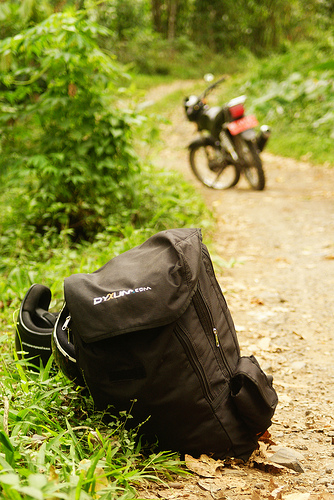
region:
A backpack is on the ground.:
[90, 226, 277, 401]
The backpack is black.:
[162, 383, 251, 430]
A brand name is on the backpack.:
[93, 285, 151, 307]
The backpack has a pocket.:
[233, 354, 277, 429]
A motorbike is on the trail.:
[182, 75, 270, 190]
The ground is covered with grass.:
[0, 428, 104, 498]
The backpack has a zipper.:
[210, 327, 220, 346]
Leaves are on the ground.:
[185, 453, 224, 476]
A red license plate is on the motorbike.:
[226, 115, 257, 135]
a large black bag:
[58, 224, 277, 460]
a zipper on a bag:
[61, 314, 72, 331]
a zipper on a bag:
[209, 325, 221, 345]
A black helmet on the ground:
[48, 299, 85, 391]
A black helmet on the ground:
[10, 281, 61, 372]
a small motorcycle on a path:
[178, 66, 273, 190]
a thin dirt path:
[111, 73, 331, 498]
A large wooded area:
[0, 1, 333, 498]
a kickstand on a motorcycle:
[206, 164, 227, 191]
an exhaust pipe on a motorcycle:
[253, 125, 272, 154]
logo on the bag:
[90, 280, 151, 303]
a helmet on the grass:
[15, 308, 51, 357]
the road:
[260, 225, 321, 285]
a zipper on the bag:
[212, 327, 225, 347]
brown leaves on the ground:
[188, 456, 236, 496]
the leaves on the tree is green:
[47, 95, 130, 188]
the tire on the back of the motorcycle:
[245, 145, 273, 188]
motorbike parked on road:
[183, 74, 270, 190]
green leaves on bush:
[2, 18, 133, 240]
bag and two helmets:
[13, 226, 277, 462]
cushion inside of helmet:
[22, 283, 52, 330]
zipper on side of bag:
[181, 252, 265, 444]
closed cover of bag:
[63, 226, 206, 340]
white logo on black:
[93, 285, 151, 303]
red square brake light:
[229, 103, 244, 118]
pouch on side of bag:
[210, 353, 279, 449]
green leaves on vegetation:
[2, 1, 331, 239]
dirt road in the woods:
[134, 78, 331, 491]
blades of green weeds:
[1, 387, 151, 496]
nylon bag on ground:
[63, 224, 278, 469]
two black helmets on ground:
[13, 281, 80, 390]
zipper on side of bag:
[195, 287, 233, 371]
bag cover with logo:
[66, 237, 203, 340]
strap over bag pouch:
[229, 354, 277, 431]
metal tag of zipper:
[212, 326, 220, 348]